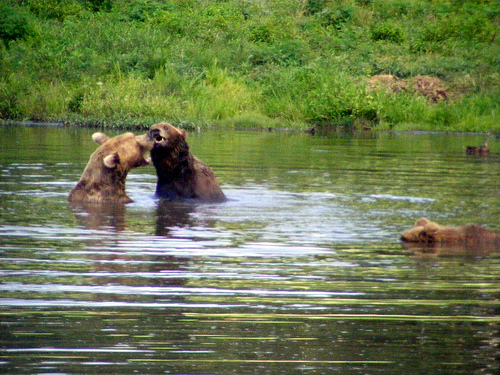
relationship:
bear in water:
[397, 213, 496, 255] [4, 118, 496, 370]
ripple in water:
[127, 284, 362, 301] [4, 118, 496, 370]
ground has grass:
[15, 76, 490, 121] [44, 62, 343, 110]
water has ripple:
[4, 118, 496, 370] [127, 284, 362, 301]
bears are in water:
[57, 124, 497, 263] [4, 118, 496, 370]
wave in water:
[234, 184, 305, 233] [4, 118, 496, 370]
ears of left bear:
[90, 130, 121, 172] [68, 120, 155, 207]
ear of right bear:
[174, 122, 194, 146] [144, 112, 229, 205]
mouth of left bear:
[139, 144, 153, 166] [68, 120, 155, 207]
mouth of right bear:
[151, 131, 167, 153] [144, 112, 229, 205]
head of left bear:
[89, 126, 156, 171] [68, 120, 155, 207]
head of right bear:
[89, 126, 156, 171] [144, 112, 229, 205]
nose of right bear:
[149, 122, 163, 136] [144, 112, 229, 205]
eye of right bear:
[161, 118, 173, 131] [144, 112, 229, 205]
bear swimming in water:
[397, 213, 496, 255] [4, 118, 496, 370]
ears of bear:
[416, 215, 438, 234] [397, 213, 496, 255]